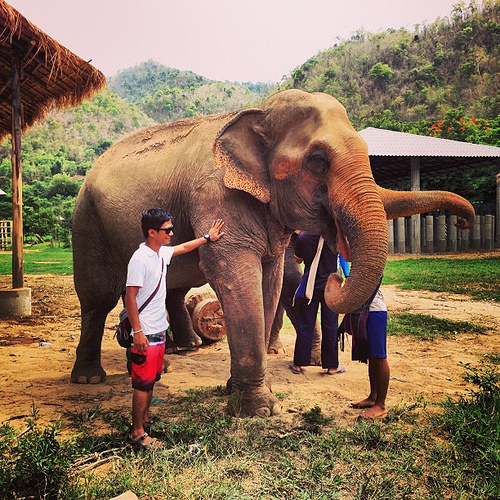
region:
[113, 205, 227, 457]
man in white shirt touching elephant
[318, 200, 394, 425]
person wearing blue shorts and white shirt near elephant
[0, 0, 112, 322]
straw roof near elephant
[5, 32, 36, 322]
thick yellow and brown wooden pole supporting roof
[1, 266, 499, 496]
light brown and yellow dry patch of dirt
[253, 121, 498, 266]
gray hut with wooden supports near elephant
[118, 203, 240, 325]
man is touching the elephant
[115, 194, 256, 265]
man is touching the elephant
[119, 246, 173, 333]
the shirt is white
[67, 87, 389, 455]
man with hand placed against elephant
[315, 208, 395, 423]
person standing behind elephant trunk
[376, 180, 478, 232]
curved elephant trunk lifted sideways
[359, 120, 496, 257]
grey roof over open structure with pole fencing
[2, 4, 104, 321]
grass roof supported by wooden pole in cement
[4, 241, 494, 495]
dirt area surrounded by green grass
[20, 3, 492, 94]
bright sky over mountains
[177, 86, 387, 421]
elephant leading with one foot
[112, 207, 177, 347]
man carrying shoulder bag with strap around body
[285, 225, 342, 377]
person wearing dark blue with white stripe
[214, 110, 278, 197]
The ear of the elephant.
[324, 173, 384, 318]
The trunk of the elephant the man in red shorts is touching.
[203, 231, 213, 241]
The watch on the man's wrist.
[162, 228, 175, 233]
The sunglasses the man is wearing.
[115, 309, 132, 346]
The black bag the man is carrying.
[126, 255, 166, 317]
The strap of the black bag the man is carrying.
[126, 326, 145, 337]
The white bracelet the man is wearing.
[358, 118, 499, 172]
The metal roof of the hut.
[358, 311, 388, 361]
The blue shorts the person is wearing.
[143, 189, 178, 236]
man has black hair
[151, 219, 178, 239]
man has black glasses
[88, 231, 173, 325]
man has white shirt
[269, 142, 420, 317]
elephant has brown trunk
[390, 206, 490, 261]
grey posts behind elephant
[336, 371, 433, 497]
green and brown ground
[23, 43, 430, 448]
this is an elephant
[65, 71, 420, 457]
the elephant is brown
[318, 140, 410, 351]
trunk of the elephant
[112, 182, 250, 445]
this is a man